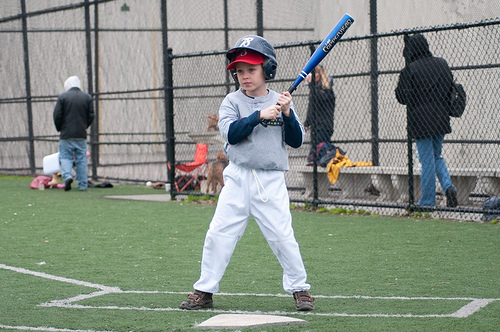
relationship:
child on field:
[29, 176, 65, 189] [0, 173, 499, 330]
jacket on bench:
[326, 147, 373, 183] [297, 165, 497, 206]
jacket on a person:
[396, 30, 454, 139] [396, 32, 459, 208]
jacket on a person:
[54, 87, 94, 137] [53, 75, 95, 188]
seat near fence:
[175, 142, 210, 194] [2, 1, 497, 221]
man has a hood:
[53, 75, 95, 188] [65, 74, 82, 90]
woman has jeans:
[303, 65, 335, 165] [307, 132, 330, 165]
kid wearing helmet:
[179, 33, 313, 315] [226, 34, 277, 80]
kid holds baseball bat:
[179, 33, 313, 315] [261, 12, 354, 127]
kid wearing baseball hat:
[179, 33, 313, 315] [227, 50, 262, 69]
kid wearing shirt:
[179, 33, 313, 315] [218, 87, 304, 173]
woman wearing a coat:
[303, 65, 335, 165] [305, 76, 334, 141]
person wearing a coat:
[53, 75, 95, 188] [54, 87, 94, 137]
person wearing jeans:
[53, 75, 95, 188] [59, 137, 89, 191]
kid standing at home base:
[179, 33, 313, 315] [195, 309, 306, 327]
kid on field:
[179, 33, 313, 315] [4, 173, 499, 330]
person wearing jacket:
[396, 32, 459, 208] [396, 30, 454, 139]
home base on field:
[195, 309, 306, 327] [4, 173, 499, 330]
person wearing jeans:
[396, 32, 459, 208] [416, 135, 452, 207]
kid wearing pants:
[179, 33, 313, 315] [193, 160, 314, 293]